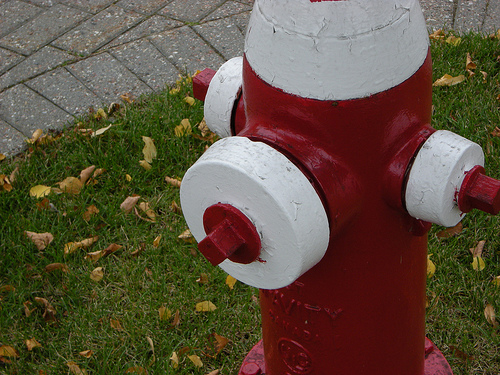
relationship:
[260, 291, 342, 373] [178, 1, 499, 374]
sign on fire hydrant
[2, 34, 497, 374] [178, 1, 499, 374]
grass around fire hydrant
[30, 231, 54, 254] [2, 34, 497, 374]
leaf in grass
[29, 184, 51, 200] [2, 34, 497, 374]
leaf in grass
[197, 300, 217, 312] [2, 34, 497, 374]
leaf in grass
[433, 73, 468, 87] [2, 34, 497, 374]
leaf in grass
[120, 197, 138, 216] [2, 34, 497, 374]
leaf in grass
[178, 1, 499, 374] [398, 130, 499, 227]
fire hydrant has side part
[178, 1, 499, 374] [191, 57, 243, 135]
fire hydrant has side part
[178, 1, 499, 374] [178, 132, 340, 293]
fire hydrant has side part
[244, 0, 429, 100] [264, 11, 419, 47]
top has cracked paint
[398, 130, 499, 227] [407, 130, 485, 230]
side part has base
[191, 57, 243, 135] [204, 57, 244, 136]
side part has base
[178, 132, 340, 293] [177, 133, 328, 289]
side part has base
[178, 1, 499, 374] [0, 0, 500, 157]
fire hydrant near sidewalk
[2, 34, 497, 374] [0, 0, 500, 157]
grass near sidewalk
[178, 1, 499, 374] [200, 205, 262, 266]
fire hydrant has bolt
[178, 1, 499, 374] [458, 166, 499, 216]
fire hydrant has bolt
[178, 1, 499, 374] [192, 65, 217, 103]
fire hydrant has bolt